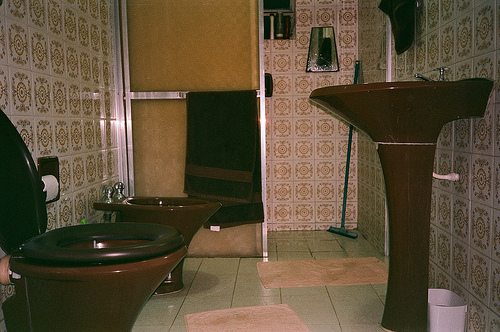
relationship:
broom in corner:
[327, 126, 360, 239] [337, 0, 370, 235]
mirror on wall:
[305, 26, 341, 71] [264, 0, 357, 232]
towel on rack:
[183, 87, 265, 228] [131, 90, 187, 104]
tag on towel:
[210, 225, 220, 232] [183, 87, 265, 228]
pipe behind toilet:
[1, 257, 21, 284] [0, 110, 187, 331]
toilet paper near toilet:
[42, 174, 59, 201] [0, 110, 187, 331]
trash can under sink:
[428, 286, 469, 331] [309, 74, 494, 331]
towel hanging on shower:
[183, 87, 265, 228] [121, 1, 267, 259]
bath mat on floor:
[256, 257, 389, 287] [135, 228, 406, 331]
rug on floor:
[184, 302, 314, 331] [135, 228, 406, 331]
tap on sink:
[414, 65, 450, 82] [309, 74, 494, 331]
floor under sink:
[135, 228, 406, 331] [309, 74, 494, 331]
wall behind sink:
[359, 0, 499, 331] [309, 74, 494, 331]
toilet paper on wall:
[42, 174, 59, 201] [1, 2, 120, 232]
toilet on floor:
[0, 110, 187, 331] [135, 228, 406, 331]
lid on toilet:
[0, 110, 48, 258] [0, 110, 187, 331]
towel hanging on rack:
[183, 87, 265, 228] [131, 90, 187, 104]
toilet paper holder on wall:
[37, 156, 61, 203] [1, 2, 120, 232]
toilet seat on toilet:
[0, 109, 184, 264] [0, 110, 187, 331]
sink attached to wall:
[309, 74, 494, 331] [359, 0, 499, 331]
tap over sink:
[414, 65, 450, 82] [309, 74, 494, 331]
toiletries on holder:
[264, 13, 291, 39] [265, 36, 294, 43]